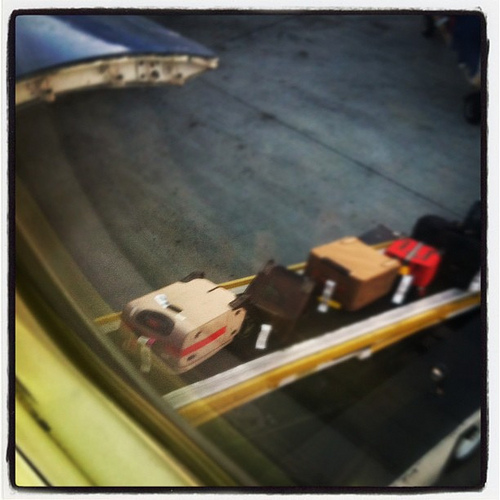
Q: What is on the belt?
A: Suitcases.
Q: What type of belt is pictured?
A: Conveyor.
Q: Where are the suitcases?
A: Conveyor belt.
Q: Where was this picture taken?
A: Inside Airplane.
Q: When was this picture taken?
A: While the plane was being loaded.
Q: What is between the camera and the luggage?
A: Window.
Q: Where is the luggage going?
A: Under plane.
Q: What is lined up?
A: Luggage.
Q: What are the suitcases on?
A: A conveyor belt.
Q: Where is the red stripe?
A: On the first suitcase.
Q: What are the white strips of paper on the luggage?
A: Luggage tags.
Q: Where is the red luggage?
A: On the conveyor belt.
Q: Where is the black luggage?
A: On the conveyor belt.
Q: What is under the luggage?
A: A conveyor belt.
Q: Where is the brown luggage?
A: On the conveyor belt.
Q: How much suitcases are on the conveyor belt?
A: Six.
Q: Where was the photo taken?
A: Inside an airplane.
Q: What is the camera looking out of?
A: A window.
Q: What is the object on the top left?
A: A door.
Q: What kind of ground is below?
A: The tarmac.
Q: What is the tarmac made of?
A: Concrete.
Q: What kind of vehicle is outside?
A: A cargo loading vehicle.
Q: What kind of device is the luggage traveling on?
A: A conveyor belt.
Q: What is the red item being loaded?
A: Luggage.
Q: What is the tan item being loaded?
A: Luggage.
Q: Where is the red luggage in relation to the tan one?
A: On the right.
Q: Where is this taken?
A: An airport.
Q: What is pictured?
A: Luggage.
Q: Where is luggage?
A: On a conveyor.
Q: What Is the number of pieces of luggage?
A: Five.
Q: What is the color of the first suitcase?
A: Beige.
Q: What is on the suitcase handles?
A: Tags.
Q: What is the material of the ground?
A: Concrete.